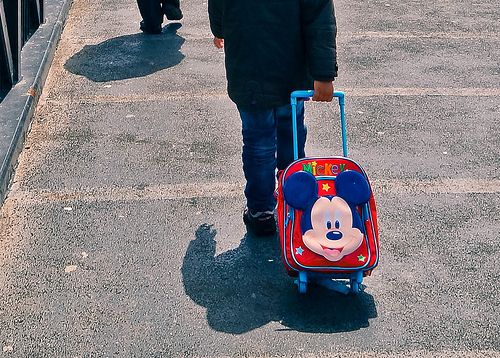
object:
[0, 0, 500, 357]
pavement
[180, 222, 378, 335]
shadow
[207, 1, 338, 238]
person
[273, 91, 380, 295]
backpack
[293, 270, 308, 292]
wheel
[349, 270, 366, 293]
wheel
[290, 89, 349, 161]
handle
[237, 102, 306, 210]
pants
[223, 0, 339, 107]
jacket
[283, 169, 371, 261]
mickey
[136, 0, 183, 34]
man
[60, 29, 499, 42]
line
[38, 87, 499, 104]
line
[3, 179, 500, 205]
line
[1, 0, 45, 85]
fence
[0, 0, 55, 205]
curb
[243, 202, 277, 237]
sneaker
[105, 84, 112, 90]
spot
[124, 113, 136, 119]
spot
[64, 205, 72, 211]
spot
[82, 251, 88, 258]
spot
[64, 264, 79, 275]
spot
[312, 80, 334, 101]
hand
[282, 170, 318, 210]
ear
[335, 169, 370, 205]
ear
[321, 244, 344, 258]
grin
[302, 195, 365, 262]
face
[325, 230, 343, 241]
nose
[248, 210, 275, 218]
edge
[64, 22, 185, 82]
shadow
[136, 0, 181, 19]
pants